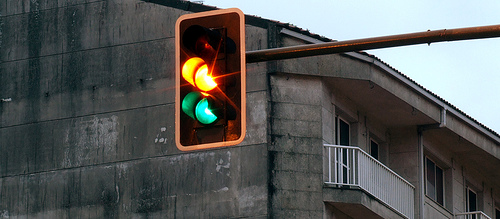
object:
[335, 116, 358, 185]
doors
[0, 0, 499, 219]
building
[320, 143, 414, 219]
railings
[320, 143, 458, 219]
balconies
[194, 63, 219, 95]
light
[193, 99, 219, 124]
light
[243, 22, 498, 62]
pole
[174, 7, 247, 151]
signal